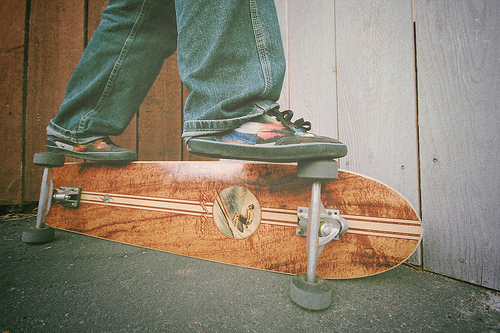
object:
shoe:
[186, 106, 348, 163]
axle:
[294, 180, 348, 283]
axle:
[28, 165, 83, 228]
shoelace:
[279, 109, 313, 133]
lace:
[277, 109, 311, 131]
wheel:
[19, 223, 56, 243]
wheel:
[32, 149, 65, 168]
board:
[20, 150, 423, 311]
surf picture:
[211, 185, 262, 240]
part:
[303, 299, 316, 306]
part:
[224, 211, 230, 221]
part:
[128, 215, 168, 239]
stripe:
[79, 189, 422, 244]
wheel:
[293, 157, 340, 180]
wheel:
[290, 273, 333, 311]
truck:
[32, 165, 54, 230]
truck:
[296, 178, 348, 285]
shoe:
[43, 134, 139, 163]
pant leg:
[48, 0, 178, 142]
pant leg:
[176, 1, 288, 139]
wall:
[6, 0, 211, 209]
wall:
[276, 1, 498, 290]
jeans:
[45, 0, 288, 148]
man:
[42, 0, 347, 163]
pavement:
[0, 212, 499, 332]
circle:
[211, 184, 262, 241]